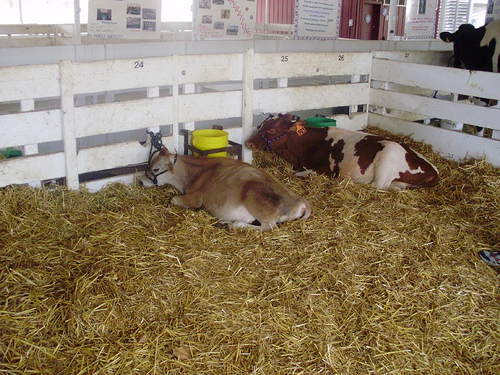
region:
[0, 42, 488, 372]
The cows are sitting on hay.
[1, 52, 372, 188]
The fence is made out of wood.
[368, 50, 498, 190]
The fence is white.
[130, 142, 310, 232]
The cow is light brown.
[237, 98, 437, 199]
The cow is brown and white.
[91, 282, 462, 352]
The hay is light brown.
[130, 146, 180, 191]
The cow is wearing a face harness.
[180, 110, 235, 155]
A yellow bucket next to the cow.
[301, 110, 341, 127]
A green bucket is next to the cow.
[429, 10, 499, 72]
The cow is black and white.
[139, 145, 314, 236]
A light brown cow.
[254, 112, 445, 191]
A dark brown cow with white spots.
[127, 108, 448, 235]
Young cows lying down in the hay.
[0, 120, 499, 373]
Yellow straw covering the ground.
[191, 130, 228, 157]
A yellow bucket.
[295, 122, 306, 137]
An orange tag with a number on it.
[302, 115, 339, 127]
A green bucket.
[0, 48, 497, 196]
A white wooden fence.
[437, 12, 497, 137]
A black and white spotted cow standing up.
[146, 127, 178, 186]
A dark colored rope around a cows head.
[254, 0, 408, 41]
maroon paneled wall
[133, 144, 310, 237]
light tan young calf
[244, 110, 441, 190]
reddish brown and white cow lying down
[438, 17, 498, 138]
black and white cow standing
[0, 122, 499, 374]
golden hay pen bedding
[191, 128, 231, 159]
bright yellow bucket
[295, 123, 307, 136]
orange tag on cows ear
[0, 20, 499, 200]
white wooden pen fencing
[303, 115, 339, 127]
green bucket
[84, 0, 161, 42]
poster with five pictures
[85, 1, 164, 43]
white poster with pictures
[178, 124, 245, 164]
yellow bucket in a black frame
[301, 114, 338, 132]
green bucket behind cow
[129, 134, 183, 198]
harness on the cows head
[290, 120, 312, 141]
orange tag on the cows ear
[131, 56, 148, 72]
the number 24 on the fence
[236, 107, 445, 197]
brown and white spotted cow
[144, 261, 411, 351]
hay or straw on the ground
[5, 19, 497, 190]
white wooden fence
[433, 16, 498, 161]
black and white cow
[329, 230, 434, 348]
Yellow hay on the ground.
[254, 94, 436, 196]
Brown and white cow.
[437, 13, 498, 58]
Black and white cow.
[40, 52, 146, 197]
Wooden white fence on pen.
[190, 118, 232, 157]
Yellow bucket by fence.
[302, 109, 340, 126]
Green bucket by fence.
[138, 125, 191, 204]
Blue rope attaching cow to fence.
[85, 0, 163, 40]
Poster with pictures in the background.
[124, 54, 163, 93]
Number on fence slat.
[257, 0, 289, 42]
Red metal wall on building.